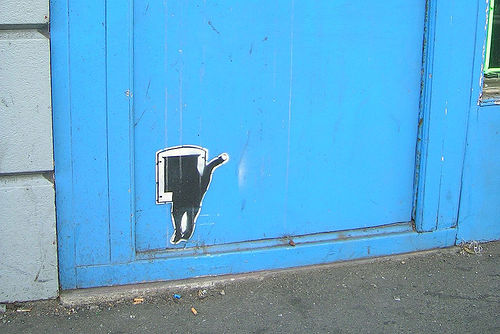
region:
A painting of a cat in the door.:
[151, 146, 226, 241]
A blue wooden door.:
[52, 0, 462, 293]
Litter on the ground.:
[117, 284, 229, 316]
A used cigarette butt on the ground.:
[188, 305, 199, 316]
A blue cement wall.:
[1, 0, 53, 302]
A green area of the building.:
[486, 2, 499, 99]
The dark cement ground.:
[92, 297, 406, 332]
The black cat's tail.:
[197, 153, 231, 185]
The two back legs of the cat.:
[168, 212, 195, 243]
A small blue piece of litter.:
[172, 293, 182, 299]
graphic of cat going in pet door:
[155, 139, 226, 245]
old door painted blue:
[53, 2, 470, 287]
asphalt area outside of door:
[13, 239, 498, 330]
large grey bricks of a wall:
[5, 0, 47, 307]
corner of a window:
[478, 0, 498, 100]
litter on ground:
[127, 283, 234, 324]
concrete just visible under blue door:
[62, 244, 469, 306]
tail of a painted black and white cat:
[202, 146, 230, 196]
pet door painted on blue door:
[154, 145, 214, 198]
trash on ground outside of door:
[453, 234, 490, 262]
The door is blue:
[56, 42, 409, 287]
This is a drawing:
[102, 124, 282, 254]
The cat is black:
[146, 125, 248, 268]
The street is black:
[28, 218, 449, 328]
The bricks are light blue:
[6, 20, 82, 282]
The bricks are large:
[0, 49, 82, 290]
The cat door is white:
[108, 83, 288, 249]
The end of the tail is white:
[211, 147, 243, 184]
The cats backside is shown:
[146, 115, 256, 272]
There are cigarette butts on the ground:
[116, 277, 211, 324]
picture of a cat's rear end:
[137, 127, 237, 246]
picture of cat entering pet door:
[143, 146, 233, 250]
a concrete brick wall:
[2, 19, 48, 305]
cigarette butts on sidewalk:
[125, 295, 231, 323]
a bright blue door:
[64, 31, 144, 281]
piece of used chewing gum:
[149, 283, 196, 303]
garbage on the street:
[453, 234, 495, 275]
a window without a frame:
[477, 2, 498, 137]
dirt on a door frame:
[235, 209, 405, 261]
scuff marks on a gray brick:
[10, 228, 60, 305]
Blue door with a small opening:
[48, 4, 499, 292]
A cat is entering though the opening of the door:
[166, 149, 241, 251]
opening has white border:
[155, 144, 209, 210]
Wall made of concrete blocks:
[0, 0, 70, 305]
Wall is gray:
[3, 5, 60, 304]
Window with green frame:
[476, 0, 499, 109]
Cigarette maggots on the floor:
[126, 290, 205, 319]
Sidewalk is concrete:
[28, 245, 498, 332]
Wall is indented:
[0, 1, 63, 304]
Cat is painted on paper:
[164, 145, 231, 255]